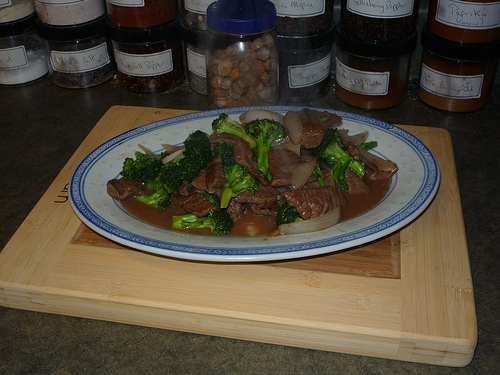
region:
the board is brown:
[228, 261, 373, 361]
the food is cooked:
[111, 107, 416, 234]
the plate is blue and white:
[65, 137, 143, 231]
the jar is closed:
[198, 4, 299, 119]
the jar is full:
[199, 3, 287, 108]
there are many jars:
[15, 5, 494, 103]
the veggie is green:
[207, 155, 267, 210]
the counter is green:
[34, 327, 134, 374]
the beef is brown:
[285, 176, 340, 226]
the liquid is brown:
[341, 182, 377, 220]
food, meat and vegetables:
[113, 111, 393, 234]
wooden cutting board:
[3, 101, 478, 364]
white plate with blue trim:
[66, 102, 440, 261]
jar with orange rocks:
[204, 1, 279, 109]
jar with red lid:
[107, 3, 185, 91]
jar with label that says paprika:
[427, 1, 498, 45]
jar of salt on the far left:
[2, 4, 45, 84]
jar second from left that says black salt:
[41, 18, 113, 88]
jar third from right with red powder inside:
[103, 1, 176, 25]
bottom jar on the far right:
[418, 27, 491, 112]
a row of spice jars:
[3, 2, 489, 116]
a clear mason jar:
[200, 0, 297, 113]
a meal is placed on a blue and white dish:
[60, 97, 496, 264]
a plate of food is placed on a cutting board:
[14, 99, 474, 354]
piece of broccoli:
[179, 211, 231, 235]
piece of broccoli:
[246, 117, 281, 171]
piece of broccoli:
[132, 186, 169, 211]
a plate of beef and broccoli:
[60, 93, 451, 243]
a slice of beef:
[285, 185, 345, 217]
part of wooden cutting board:
[356, 249, 474, 374]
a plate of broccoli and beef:
[69, 68, 466, 306]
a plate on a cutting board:
[24, 83, 477, 373]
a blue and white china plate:
[71, 94, 448, 267]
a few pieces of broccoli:
[128, 129, 234, 214]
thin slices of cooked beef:
[226, 151, 337, 226]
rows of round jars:
[9, 0, 491, 133]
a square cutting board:
[1, 100, 495, 369]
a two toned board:
[28, 103, 498, 365]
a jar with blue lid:
[194, 0, 292, 107]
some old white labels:
[288, 48, 420, 108]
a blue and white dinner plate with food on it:
[65, 93, 445, 268]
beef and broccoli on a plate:
[66, 92, 445, 274]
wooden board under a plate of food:
[7, 89, 479, 372]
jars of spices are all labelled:
[3, 0, 499, 120]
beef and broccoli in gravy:
[98, 115, 407, 254]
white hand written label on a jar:
[103, 38, 185, 81]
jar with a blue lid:
[200, 0, 287, 121]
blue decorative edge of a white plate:
[59, 102, 445, 262]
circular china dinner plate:
[63, 94, 447, 265]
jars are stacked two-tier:
[0, 0, 497, 117]